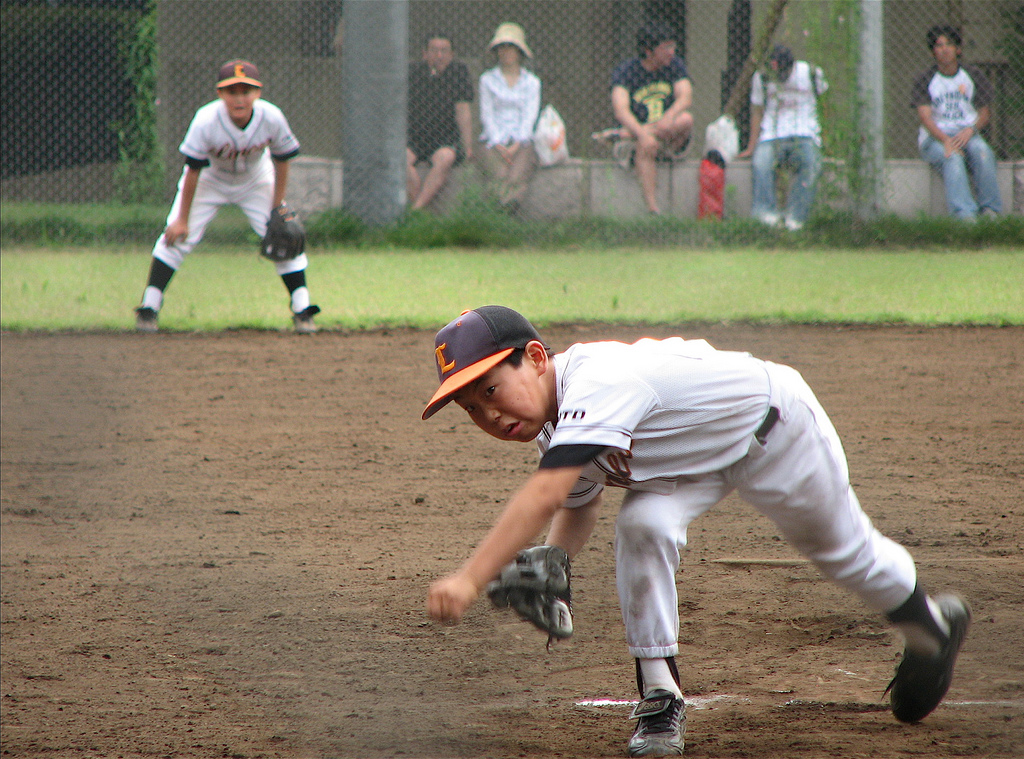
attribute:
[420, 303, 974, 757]
boy — young, standing, leaning, bending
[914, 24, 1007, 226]
man — sitting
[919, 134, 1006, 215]
jeans — blue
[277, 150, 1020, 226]
wall — short, concrete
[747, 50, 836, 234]
man — sitting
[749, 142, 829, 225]
jeans — blue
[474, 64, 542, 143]
shirt — white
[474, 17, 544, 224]
woman — sitting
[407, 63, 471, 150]
shirt — black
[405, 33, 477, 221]
man — sitting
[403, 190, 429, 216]
ankles — crossed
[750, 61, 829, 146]
shirt — white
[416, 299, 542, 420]
hat — black, yellow, orange, orage, white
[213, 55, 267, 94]
hat — black, yellow, orange, orage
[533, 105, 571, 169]
bag — white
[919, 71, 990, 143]
shirt — white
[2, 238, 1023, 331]
grass — growing, green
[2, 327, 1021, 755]
dirt — brown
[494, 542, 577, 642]
glove — black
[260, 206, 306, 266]
glove — black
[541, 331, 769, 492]
jersey — white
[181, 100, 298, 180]
jersey — white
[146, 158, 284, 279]
pants — white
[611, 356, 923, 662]
pants — white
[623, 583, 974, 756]
shoes — black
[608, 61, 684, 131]
shirt — black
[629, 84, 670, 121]
logo — yellow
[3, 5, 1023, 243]
fence — metal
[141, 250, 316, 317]
socks — black, white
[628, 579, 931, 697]
socks — black, white